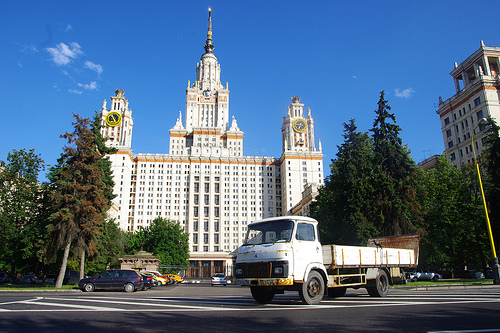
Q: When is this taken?
A: Daytime.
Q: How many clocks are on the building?
A: Two.